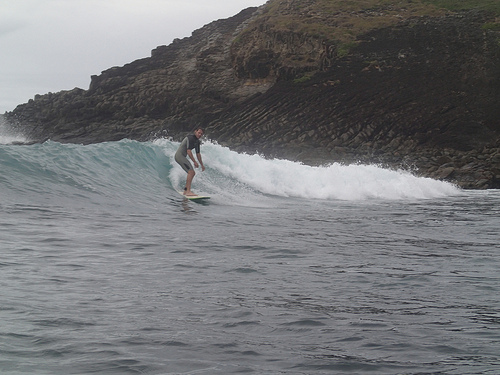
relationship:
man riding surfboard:
[168, 122, 211, 192] [190, 194, 214, 204]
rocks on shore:
[171, 40, 381, 119] [274, 122, 445, 190]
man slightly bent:
[168, 122, 211, 192] [172, 143, 185, 161]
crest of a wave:
[226, 144, 258, 171] [252, 146, 311, 190]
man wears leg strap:
[168, 122, 211, 192] [183, 186, 190, 193]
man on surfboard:
[168, 122, 211, 192] [190, 194, 214, 204]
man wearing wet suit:
[168, 122, 211, 192] [167, 134, 206, 177]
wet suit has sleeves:
[167, 134, 206, 177] [183, 137, 197, 152]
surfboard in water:
[190, 194, 214, 204] [231, 223, 341, 304]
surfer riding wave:
[168, 122, 211, 192] [252, 146, 311, 190]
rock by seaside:
[250, 76, 327, 150] [260, 144, 331, 195]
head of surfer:
[194, 124, 207, 140] [168, 122, 211, 192]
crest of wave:
[226, 144, 258, 171] [252, 146, 311, 190]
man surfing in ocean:
[168, 122, 211, 192] [261, 182, 400, 256]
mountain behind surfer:
[164, 1, 401, 123] [168, 122, 211, 192]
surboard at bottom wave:
[190, 194, 214, 204] [9, 130, 457, 221]